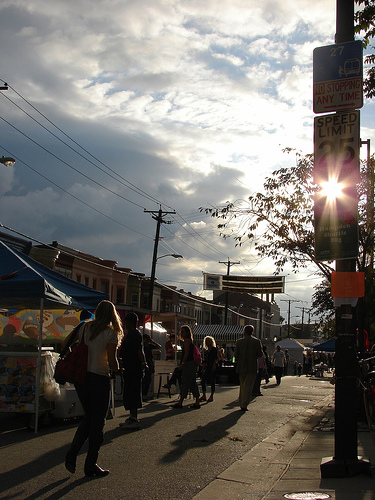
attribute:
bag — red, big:
[67, 338, 94, 392]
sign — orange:
[321, 270, 370, 297]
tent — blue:
[8, 244, 78, 316]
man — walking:
[246, 321, 263, 398]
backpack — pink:
[193, 339, 210, 364]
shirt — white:
[266, 346, 280, 364]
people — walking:
[97, 327, 279, 365]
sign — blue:
[323, 52, 370, 81]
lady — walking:
[68, 300, 119, 462]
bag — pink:
[193, 343, 205, 370]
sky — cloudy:
[45, 36, 167, 174]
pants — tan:
[225, 362, 259, 412]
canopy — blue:
[4, 251, 57, 311]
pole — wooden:
[334, 338, 366, 476]